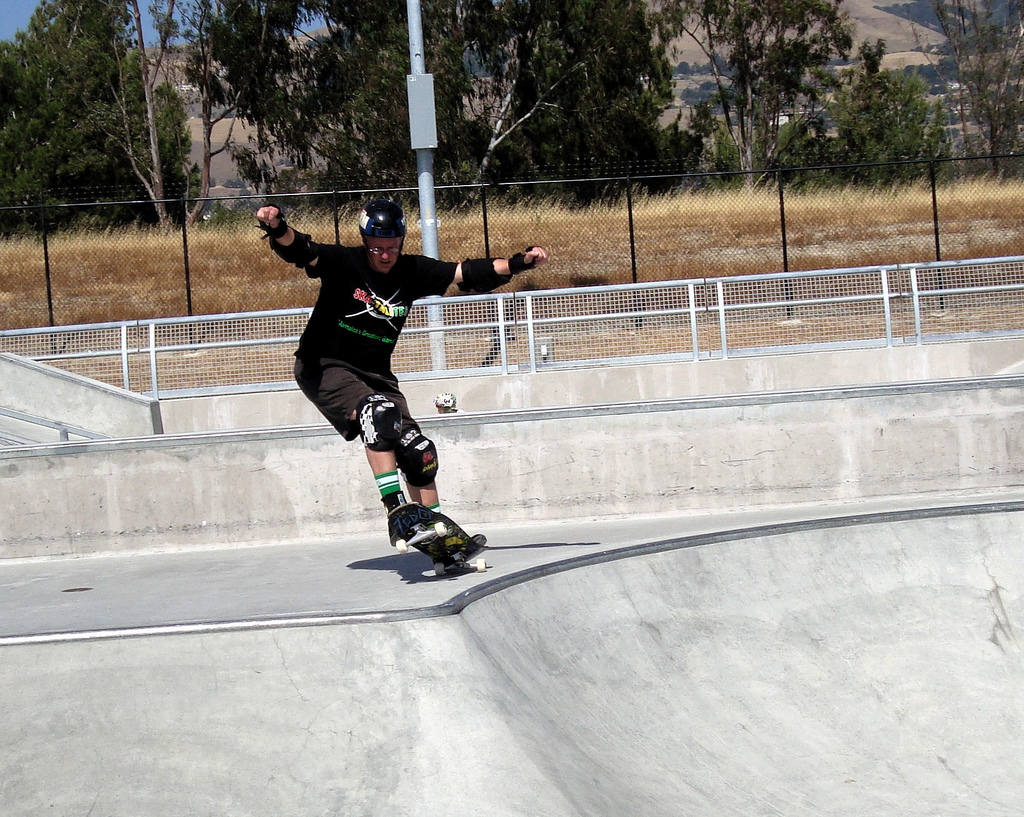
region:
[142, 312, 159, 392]
fence has a white rail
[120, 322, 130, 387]
fence has a white rail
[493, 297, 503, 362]
fence has a white rail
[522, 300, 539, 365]
fence has a white rail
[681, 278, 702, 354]
fence has a white rail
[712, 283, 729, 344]
fence has a white rail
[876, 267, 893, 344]
fence has a white rail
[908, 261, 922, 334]
fence has a white rail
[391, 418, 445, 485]
skateboarder is wearing protective knee pads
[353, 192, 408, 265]
skateboarder is wearing protective safety helmet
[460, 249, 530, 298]
man is wearing protective elbow pads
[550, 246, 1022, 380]
metal fence railing in the skate park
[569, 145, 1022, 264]
black chain link fence outside the park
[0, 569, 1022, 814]
concrete skate ramp in the park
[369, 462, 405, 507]
man is wearing green and white striped socks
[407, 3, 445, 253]
metal light post outside the fence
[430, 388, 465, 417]
skateboarders grey protective safety helmet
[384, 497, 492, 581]
black skateboard with white polyurethane wheels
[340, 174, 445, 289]
head of the man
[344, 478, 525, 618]
board under the man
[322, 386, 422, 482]
knee pad on the man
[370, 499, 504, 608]
wheels on the board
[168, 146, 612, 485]
man with arms out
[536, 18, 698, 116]
many leaveson the tree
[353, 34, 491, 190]
silver pole on ground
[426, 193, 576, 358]
arm of the man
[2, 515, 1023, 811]
Concave surface for skateboarding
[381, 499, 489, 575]
Skateboard being used in jump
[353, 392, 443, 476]
Knee pads protecting skateboarder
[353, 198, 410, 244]
Helmet protecting skateboarder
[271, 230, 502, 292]
Elbow pads protecting skateboarder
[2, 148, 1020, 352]
Dark fence enclosing area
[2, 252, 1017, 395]
Steel fence enclosing concrete skateboarding area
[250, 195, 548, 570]
Man attempting skateboarding jump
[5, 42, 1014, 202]
Trees outside of the skateboard area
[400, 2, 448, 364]
Utility pole outside the skateboard area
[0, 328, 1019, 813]
the place is cement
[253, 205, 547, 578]
the guy is skating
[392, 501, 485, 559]
the board is black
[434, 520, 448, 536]
the wheel is white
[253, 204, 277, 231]
hand of a man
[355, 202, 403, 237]
black and white helmet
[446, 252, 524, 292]
arm of a man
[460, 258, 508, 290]
the pad is black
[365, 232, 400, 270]
face of a man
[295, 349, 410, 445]
the shorts are brown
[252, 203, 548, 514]
A man riding a skateboard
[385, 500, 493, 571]
A skateboard in a skate park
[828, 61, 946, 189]
A tree in a field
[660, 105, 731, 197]
A tree in a field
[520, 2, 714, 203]
A tree in a field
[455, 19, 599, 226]
A tree in a field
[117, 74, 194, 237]
A tree in a field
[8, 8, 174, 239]
A tree in a field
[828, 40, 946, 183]
A tree in a field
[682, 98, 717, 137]
A tree in a field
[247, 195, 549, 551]
The man on the skateboard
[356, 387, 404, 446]
The kneepad on the man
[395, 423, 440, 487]
The kneepad on the man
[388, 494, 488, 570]
The skateboard under the man